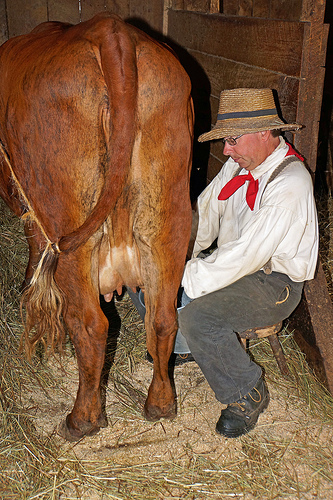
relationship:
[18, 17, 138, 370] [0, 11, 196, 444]
rope of animal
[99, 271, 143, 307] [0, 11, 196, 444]
teat of animal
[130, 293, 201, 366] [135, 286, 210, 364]
surface of bucket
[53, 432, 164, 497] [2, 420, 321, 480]
straw of ground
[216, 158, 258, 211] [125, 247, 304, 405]
handkerchief holding pants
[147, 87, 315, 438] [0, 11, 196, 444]
man milking animal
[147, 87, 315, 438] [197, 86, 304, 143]
man wearing hat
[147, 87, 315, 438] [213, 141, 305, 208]
man wearing handkerchief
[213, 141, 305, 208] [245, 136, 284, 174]
handkerchief around neck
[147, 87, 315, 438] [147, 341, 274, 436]
man wearing boots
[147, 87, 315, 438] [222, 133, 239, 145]
man wearing glasses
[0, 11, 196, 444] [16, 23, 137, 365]
animal has tail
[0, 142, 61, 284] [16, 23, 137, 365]
rope on tail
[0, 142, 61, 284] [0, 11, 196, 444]
rope on animal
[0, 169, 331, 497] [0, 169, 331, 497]
hay on hay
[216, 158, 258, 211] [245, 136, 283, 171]
handkerchief around neck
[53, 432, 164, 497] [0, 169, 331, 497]
straw on hay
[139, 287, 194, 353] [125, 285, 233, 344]
bucket between knees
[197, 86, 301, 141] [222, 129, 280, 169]
hat on head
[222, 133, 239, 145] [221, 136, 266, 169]
glasses on face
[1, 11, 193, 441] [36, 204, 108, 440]
animal has leg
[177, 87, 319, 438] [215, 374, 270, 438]
man wearing boot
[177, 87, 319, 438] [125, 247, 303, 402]
man wearing pants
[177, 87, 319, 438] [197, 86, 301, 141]
man wearing hat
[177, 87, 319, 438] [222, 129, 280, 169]
man has head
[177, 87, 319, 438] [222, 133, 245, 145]
man wearing glasses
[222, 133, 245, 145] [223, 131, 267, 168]
glasses on face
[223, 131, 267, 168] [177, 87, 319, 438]
face on man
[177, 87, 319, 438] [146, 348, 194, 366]
man wearing boot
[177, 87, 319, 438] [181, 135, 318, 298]
man wearing shirt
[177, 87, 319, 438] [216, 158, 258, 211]
man wearing handkerchief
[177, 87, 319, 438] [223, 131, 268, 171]
man on face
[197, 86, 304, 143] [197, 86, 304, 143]
hat on hat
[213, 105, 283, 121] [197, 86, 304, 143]
band around hat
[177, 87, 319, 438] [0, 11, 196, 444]
man milking animal